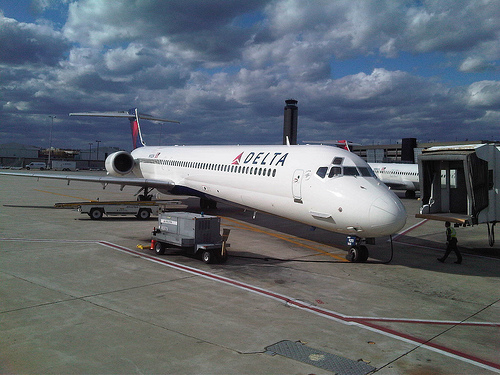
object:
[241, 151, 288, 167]
delta logo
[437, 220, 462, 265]
man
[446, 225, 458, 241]
safety vest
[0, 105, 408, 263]
plane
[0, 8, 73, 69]
clouds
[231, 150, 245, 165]
insignia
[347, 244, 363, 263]
wheel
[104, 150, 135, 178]
engine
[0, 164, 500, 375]
tarmac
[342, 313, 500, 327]
lines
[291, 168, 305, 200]
door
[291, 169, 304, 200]
exit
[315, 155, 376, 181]
cockpit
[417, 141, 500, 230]
tunnel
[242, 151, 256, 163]
letters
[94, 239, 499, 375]
line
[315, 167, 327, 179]
windows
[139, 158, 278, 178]
row